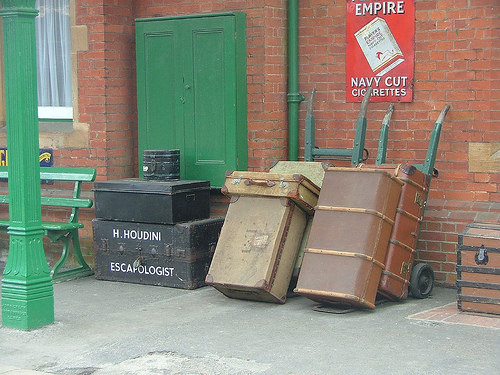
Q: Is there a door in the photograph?
A: Yes, there are doors.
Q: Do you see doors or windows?
A: Yes, there are doors.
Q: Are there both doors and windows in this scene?
A: Yes, there are both doors and a window.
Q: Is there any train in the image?
A: No, there are no trains.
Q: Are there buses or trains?
A: No, there are no trains or buses.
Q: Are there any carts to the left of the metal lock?
A: Yes, there is a cart to the left of the lock.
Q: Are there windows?
A: Yes, there is a window.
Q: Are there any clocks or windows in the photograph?
A: Yes, there is a window.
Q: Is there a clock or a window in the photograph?
A: Yes, there is a window.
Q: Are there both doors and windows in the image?
A: Yes, there are both a window and a door.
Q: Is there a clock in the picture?
A: No, there are no clocks.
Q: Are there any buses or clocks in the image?
A: No, there are no clocks or buses.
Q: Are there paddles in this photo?
A: No, there are no paddles.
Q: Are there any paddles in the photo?
A: No, there are no paddles.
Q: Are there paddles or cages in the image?
A: No, there are no paddles or cages.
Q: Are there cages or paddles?
A: No, there are no paddles or cages.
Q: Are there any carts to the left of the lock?
A: Yes, there is a cart to the left of the lock.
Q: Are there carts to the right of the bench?
A: Yes, there is a cart to the right of the bench.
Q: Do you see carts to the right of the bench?
A: Yes, there is a cart to the right of the bench.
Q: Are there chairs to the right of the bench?
A: No, there is a cart to the right of the bench.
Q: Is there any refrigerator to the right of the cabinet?
A: No, there is a cart to the right of the cabinet.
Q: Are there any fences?
A: No, there are no fences.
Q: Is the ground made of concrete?
A: Yes, the ground is made of concrete.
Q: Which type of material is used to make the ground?
A: The ground is made of concrete.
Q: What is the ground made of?
A: The ground is made of concrete.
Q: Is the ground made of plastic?
A: No, the ground is made of concrete.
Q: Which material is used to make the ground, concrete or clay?
A: The ground is made of concrete.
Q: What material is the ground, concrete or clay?
A: The ground is made of concrete.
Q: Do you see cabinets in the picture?
A: Yes, there is a cabinet.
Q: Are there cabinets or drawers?
A: Yes, there is a cabinet.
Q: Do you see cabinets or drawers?
A: Yes, there is a cabinet.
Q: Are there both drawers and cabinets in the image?
A: No, there is a cabinet but no drawers.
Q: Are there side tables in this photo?
A: No, there are no side tables.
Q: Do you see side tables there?
A: No, there are no side tables.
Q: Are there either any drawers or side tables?
A: No, there are no side tables or drawers.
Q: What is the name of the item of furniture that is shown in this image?
A: The piece of furniture is a cabinet.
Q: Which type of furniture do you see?
A: The furniture is a cabinet.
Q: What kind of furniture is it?
A: The piece of furniture is a cabinet.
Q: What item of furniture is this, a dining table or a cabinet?
A: This is a cabinet.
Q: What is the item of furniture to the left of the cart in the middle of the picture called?
A: The piece of furniture is a cabinet.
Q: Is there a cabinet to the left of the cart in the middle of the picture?
A: Yes, there is a cabinet to the left of the cart.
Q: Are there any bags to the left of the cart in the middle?
A: No, there is a cabinet to the left of the cart.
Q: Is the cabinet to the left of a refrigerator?
A: No, the cabinet is to the left of a cart.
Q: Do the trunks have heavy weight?
A: Yes, the trunks are heavy.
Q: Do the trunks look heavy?
A: Yes, the trunks are heavy.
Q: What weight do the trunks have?
A: The trunks have heavy weight.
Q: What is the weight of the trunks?
A: The trunks are heavy.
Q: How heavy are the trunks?
A: The trunks are heavy.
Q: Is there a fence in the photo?
A: No, there are no fences.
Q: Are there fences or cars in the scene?
A: No, there are no fences or cars.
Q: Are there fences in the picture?
A: No, there are no fences.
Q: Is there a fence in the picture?
A: No, there are no fences.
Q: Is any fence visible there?
A: No, there are no fences.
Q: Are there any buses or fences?
A: No, there are no fences or buses.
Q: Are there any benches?
A: Yes, there is a bench.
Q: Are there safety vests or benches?
A: Yes, there is a bench.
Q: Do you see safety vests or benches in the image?
A: Yes, there is a bench.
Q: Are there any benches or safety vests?
A: Yes, there is a bench.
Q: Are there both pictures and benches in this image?
A: No, there is a bench but no pictures.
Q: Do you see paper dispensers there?
A: No, there are no paper dispensers.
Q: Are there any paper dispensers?
A: No, there are no paper dispensers.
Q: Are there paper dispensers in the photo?
A: No, there are no paper dispensers.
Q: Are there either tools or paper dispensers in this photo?
A: No, there are no paper dispensers or tools.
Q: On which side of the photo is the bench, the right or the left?
A: The bench is on the left of the image.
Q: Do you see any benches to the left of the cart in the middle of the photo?
A: Yes, there is a bench to the left of the cart.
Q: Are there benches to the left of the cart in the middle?
A: Yes, there is a bench to the left of the cart.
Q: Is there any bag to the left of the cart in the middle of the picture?
A: No, there is a bench to the left of the cart.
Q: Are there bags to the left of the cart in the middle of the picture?
A: No, there is a bench to the left of the cart.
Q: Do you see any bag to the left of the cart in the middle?
A: No, there is a bench to the left of the cart.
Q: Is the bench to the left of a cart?
A: Yes, the bench is to the left of a cart.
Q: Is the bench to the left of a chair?
A: No, the bench is to the left of a cart.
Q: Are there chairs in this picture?
A: No, there are no chairs.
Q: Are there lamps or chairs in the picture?
A: No, there are no chairs or lamps.